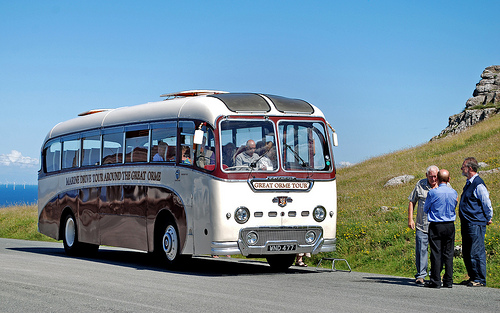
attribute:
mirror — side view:
[191, 126, 212, 149]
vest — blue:
[457, 180, 488, 220]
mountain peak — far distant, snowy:
[423, 61, 498, 149]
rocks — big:
[382, 168, 416, 186]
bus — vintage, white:
[33, 89, 341, 265]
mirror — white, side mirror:
[189, 123, 205, 154]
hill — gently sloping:
[312, 63, 498, 285]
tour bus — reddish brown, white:
[26, 90, 360, 284]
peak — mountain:
[1, 148, 41, 166]